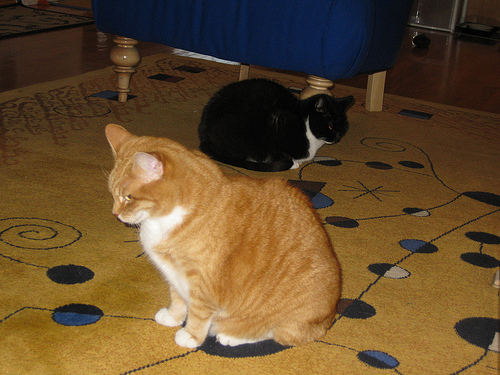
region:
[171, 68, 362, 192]
black cat on floor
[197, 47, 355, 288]
black cat on floor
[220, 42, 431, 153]
black cat on floor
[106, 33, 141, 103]
decorative wooden table leg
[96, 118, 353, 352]
yellow and white tabby cat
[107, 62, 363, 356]
two cats sitting on a floor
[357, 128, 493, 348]
white, black and blue patterns on a yellow carpet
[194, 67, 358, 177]
black and white house cat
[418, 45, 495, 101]
shiny hardwood floors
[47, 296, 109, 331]
black and blue circle woven into carpet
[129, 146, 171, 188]
ear of a yellow cat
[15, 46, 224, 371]
a yellow carpet on the floor with yellow cat sitting on it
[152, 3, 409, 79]
blue cushion on a couch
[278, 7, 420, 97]
blue cloth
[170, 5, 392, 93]
blue cloth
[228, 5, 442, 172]
blue cloth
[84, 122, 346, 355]
a brown and white cat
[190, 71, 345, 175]
a black and white cat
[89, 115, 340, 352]
a cat sitting on rug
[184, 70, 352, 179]
a cat laying on rug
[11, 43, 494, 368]
a brown rug with dot pattern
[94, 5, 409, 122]
a dark blue piece of furniture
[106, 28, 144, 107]
a blonde wooden leg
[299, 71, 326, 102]
a blonde wooden leg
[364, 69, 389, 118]
a blonde wooden leg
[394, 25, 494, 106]
hardwood flooring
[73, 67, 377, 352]
Two cats sitting on a rug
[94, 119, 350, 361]
Tan and white cat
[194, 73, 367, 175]
Black and white cat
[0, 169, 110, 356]
Tan rug with blue and black dots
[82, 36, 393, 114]
Wooden legs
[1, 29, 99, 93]
Hardwood floors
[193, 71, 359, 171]
Black cat with a white chest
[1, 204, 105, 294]
Black dot with a black swirl design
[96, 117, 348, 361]
Tan cat with white chest and feet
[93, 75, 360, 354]
One cat lying down and one cat sitting up